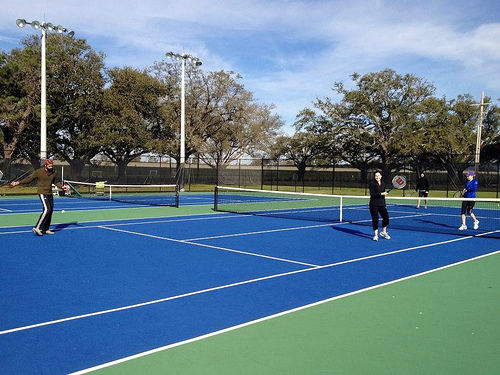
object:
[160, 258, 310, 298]
line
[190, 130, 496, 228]
net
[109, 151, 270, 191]
fence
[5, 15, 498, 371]
court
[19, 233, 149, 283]
area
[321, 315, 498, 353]
area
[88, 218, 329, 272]
line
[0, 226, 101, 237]
line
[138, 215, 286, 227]
line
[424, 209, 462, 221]
line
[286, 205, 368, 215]
line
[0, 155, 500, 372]
tennis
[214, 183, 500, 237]
tennis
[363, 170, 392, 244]
woman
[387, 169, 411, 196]
tennis racket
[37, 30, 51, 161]
silver pole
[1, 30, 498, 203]
outside the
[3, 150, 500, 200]
tennis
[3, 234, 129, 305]
tennis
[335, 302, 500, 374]
outside the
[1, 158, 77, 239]
man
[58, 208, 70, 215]
tennis ball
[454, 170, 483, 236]
person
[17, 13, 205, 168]
lighting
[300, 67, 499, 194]
green tree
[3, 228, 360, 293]
white, blue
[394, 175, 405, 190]
white and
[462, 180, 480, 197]
blue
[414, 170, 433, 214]
man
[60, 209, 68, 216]
air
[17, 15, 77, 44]
lights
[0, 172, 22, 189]
raquet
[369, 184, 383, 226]
black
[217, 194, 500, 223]
white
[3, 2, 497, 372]
park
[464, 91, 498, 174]
telephone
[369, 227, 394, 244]
white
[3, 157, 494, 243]
four persons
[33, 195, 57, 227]
tennis pants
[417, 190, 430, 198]
black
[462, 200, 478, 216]
capri pants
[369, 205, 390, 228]
athletic pants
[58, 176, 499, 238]
stretched across